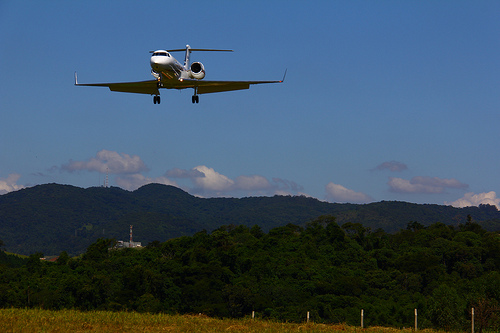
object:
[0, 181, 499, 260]
hill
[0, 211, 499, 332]
trees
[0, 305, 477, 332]
grass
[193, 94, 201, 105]
wheel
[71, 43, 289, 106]
plane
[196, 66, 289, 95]
wing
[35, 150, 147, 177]
clouds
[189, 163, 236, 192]
clouds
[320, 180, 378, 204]
clouds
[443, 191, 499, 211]
clouds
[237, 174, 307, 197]
clouds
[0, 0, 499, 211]
blue sky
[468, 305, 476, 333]
poles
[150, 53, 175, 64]
nose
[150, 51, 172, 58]
windshield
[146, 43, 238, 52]
tail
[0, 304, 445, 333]
ground